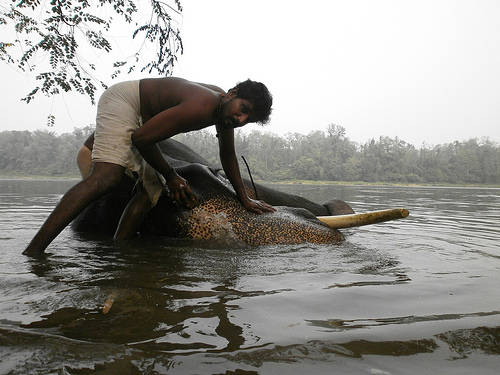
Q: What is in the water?
A: An elephant.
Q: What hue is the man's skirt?
A: White.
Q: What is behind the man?
A: Tree with branches and leaves.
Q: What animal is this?
A: An elephant.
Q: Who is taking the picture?
A: A photographer.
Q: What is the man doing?
A: Bathing an elephant.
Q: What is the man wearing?
A: Shorts.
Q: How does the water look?
A: Brown and calm.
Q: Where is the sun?
A: Behind the clouds.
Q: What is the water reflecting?
A: The sky.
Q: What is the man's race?
A: Indian.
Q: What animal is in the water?
A: Elephant.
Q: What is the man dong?
A: Leaning on the elephant.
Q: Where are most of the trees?
A: On the other side of the water.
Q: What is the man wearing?
A: White shorts.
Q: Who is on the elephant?
A: The male.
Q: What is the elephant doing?
A: Bathing.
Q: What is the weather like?
A: Hazy.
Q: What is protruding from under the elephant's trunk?
A: Tusk.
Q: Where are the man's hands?
A: On the elephant's trunk.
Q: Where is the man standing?
A: In the water by the elephant.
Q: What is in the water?
A: An elephant.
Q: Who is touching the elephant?
A: The man.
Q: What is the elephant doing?
A: Laying in the water.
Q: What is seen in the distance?
A: Trees and foliage.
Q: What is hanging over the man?
A: Leaves and stems.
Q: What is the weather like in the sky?
A: Cloudy and overcast.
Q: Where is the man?
A: In the water.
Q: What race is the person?
A: Indian.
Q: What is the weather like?
A: Clear.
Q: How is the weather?
A: Cloudy.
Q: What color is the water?
A: Green.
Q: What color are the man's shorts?
A: White.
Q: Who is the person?
A: A man.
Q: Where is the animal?
A: In the water.